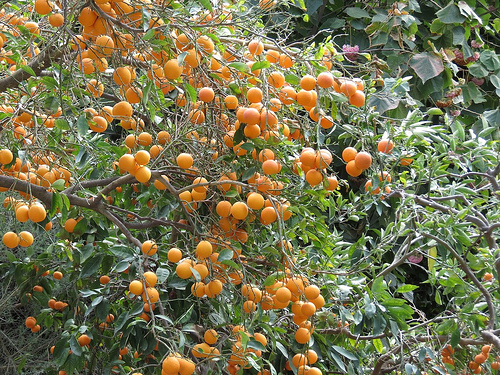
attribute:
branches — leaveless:
[87, 7, 253, 104]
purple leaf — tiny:
[339, 42, 361, 62]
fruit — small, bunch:
[352, 151, 369, 166]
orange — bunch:
[210, 76, 281, 154]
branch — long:
[2, 167, 276, 284]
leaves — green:
[340, 290, 395, 334]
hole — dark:
[387, 252, 450, 329]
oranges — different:
[215, 82, 292, 150]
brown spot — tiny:
[55, 203, 61, 214]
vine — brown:
[141, 122, 188, 207]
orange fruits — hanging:
[89, 12, 361, 210]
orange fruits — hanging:
[152, 243, 312, 373]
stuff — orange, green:
[56, 25, 391, 325]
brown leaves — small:
[386, 3, 408, 18]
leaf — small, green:
[184, 342, 226, 361]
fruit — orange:
[3, 2, 408, 373]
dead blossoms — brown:
[433, 86, 468, 116]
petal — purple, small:
[408, 248, 423, 265]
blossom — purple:
[338, 42, 360, 60]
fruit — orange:
[236, 75, 280, 123]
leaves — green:
[333, 12, 458, 126]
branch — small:
[111, 138, 338, 229]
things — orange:
[140, 148, 344, 353]